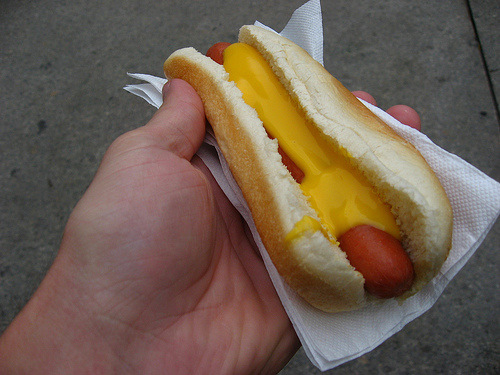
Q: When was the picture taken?
A: During the day.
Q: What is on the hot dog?
A: Mustard.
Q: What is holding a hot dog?
A: A hand.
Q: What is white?
A: Napkin.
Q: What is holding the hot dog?
A: Hot dog bun.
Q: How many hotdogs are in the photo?
A: One.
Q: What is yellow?
A: The mustard.